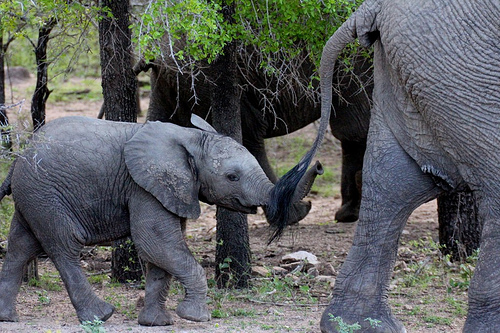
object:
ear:
[120, 118, 201, 221]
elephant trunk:
[245, 150, 341, 223]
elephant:
[0, 110, 321, 332]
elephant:
[265, 0, 497, 332]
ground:
[19, 77, 493, 307]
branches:
[201, 43, 301, 120]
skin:
[308, 1, 498, 331]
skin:
[0, 121, 325, 330]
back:
[22, 114, 149, 174]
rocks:
[276, 261, 335, 275]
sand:
[247, 312, 305, 328]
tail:
[265, 3, 380, 257]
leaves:
[170, 14, 327, 69]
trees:
[93, 0, 144, 258]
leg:
[320, 106, 427, 331]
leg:
[454, 176, 498, 331]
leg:
[128, 186, 211, 321]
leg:
[140, 260, 176, 324]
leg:
[45, 222, 115, 320]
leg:
[0, 218, 37, 316]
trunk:
[263, 159, 320, 209]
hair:
[258, 147, 332, 247]